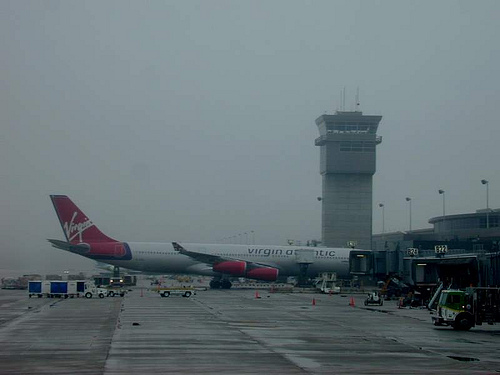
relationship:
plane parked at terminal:
[46, 192, 372, 289] [350, 241, 500, 285]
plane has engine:
[46, 192, 372, 289] [214, 259, 277, 280]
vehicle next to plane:
[155, 283, 198, 300] [46, 192, 372, 289]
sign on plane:
[248, 246, 337, 257] [46, 192, 372, 289]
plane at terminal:
[46, 192, 372, 289] [350, 241, 500, 285]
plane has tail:
[46, 192, 372, 289] [48, 192, 128, 264]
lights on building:
[380, 177, 491, 231] [314, 207, 500, 285]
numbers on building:
[435, 245, 449, 254] [314, 207, 500, 285]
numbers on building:
[407, 247, 419, 256] [314, 207, 500, 285]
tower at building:
[315, 83, 385, 248] [314, 207, 500, 285]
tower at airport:
[315, 83, 385, 248] [307, 211, 499, 280]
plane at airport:
[46, 192, 372, 289] [307, 211, 499, 280]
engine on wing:
[214, 259, 277, 280] [171, 241, 285, 280]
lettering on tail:
[62, 211, 94, 243] [48, 192, 128, 264]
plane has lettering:
[46, 192, 372, 289] [62, 211, 94, 243]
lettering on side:
[248, 246, 337, 257] [80, 241, 367, 271]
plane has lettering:
[46, 192, 372, 289] [248, 246, 337, 257]